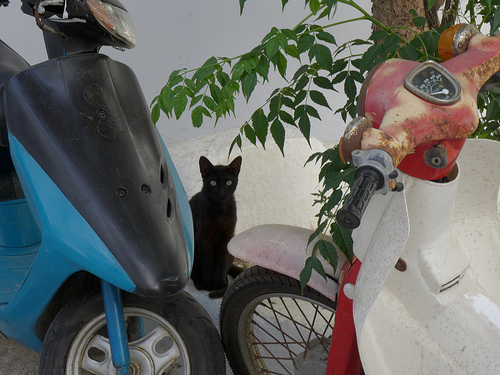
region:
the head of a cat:
[192, 129, 289, 201]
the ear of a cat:
[187, 148, 277, 182]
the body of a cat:
[189, 137, 271, 292]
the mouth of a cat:
[209, 174, 236, 214]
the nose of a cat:
[198, 187, 238, 212]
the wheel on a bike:
[38, 312, 238, 363]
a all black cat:
[156, 111, 283, 335]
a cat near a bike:
[190, 80, 412, 312]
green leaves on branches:
[148, 3, 448, 160]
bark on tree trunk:
[369, 0, 424, 47]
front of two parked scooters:
[5, 2, 495, 371]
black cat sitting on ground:
[189, 154, 243, 296]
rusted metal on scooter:
[373, 39, 496, 163]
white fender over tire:
[222, 223, 340, 372]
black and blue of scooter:
[3, 54, 194, 362]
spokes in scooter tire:
[245, 298, 329, 373]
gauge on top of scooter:
[407, 58, 461, 105]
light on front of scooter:
[94, 2, 135, 42]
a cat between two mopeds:
[44, 76, 409, 316]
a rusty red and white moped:
[221, 23, 495, 367]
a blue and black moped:
[8, 28, 202, 365]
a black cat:
[173, 151, 257, 300]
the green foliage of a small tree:
[153, 33, 365, 144]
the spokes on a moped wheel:
[253, 301, 313, 361]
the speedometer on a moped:
[404, 51, 464, 114]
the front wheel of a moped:
[38, 278, 220, 373]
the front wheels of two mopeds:
[38, 222, 358, 371]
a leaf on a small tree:
[266, 118, 291, 160]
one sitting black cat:
[192, 148, 241, 298]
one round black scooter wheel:
[28, 283, 225, 374]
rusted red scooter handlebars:
[330, 24, 499, 229]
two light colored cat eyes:
[205, 173, 234, 188]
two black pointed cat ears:
[197, 154, 246, 169]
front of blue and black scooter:
[8, 2, 211, 374]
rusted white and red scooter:
[226, 40, 498, 372]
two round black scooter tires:
[36, 271, 339, 373]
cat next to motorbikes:
[189, 151, 244, 298]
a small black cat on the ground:
[186, 154, 241, 298]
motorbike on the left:
[1, 0, 223, 372]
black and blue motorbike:
[0, 3, 225, 374]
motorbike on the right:
[221, 23, 498, 372]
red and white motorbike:
[218, 23, 497, 371]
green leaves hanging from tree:
[145, 1, 498, 288]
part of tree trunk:
[370, 1, 432, 78]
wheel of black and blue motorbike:
[39, 286, 227, 372]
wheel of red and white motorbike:
[223, 268, 332, 371]